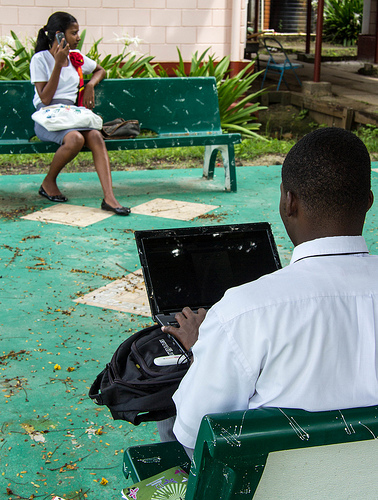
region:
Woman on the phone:
[22, 7, 136, 214]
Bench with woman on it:
[3, 76, 248, 147]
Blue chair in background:
[249, 30, 305, 84]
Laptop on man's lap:
[125, 222, 293, 330]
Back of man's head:
[262, 126, 373, 298]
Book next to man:
[118, 467, 187, 494]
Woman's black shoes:
[33, 180, 122, 212]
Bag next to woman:
[99, 108, 144, 138]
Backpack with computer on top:
[99, 317, 167, 414]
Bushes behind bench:
[111, 32, 261, 135]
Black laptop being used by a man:
[119, 200, 304, 325]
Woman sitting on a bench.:
[23, 20, 139, 233]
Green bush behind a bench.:
[155, 46, 270, 140]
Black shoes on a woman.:
[25, 177, 179, 227]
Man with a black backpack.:
[93, 321, 206, 416]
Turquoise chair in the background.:
[256, 35, 315, 96]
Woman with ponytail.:
[26, 11, 76, 54]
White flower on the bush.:
[107, 28, 149, 56]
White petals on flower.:
[101, 26, 182, 71]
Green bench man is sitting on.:
[199, 415, 368, 481]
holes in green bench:
[160, 86, 226, 129]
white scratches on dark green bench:
[282, 413, 319, 453]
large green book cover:
[103, 462, 219, 498]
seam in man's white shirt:
[192, 303, 301, 396]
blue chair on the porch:
[260, 24, 313, 89]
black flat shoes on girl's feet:
[91, 188, 158, 221]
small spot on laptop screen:
[163, 241, 202, 255]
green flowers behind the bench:
[187, 43, 302, 150]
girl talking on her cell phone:
[42, 22, 79, 57]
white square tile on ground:
[13, 184, 165, 244]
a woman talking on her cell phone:
[18, 8, 142, 218]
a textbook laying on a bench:
[105, 468, 203, 498]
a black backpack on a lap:
[87, 325, 193, 427]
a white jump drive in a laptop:
[154, 344, 194, 374]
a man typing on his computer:
[127, 127, 374, 416]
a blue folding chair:
[261, 25, 308, 90]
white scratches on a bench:
[273, 411, 342, 449]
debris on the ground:
[38, 431, 88, 485]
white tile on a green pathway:
[24, 200, 110, 236]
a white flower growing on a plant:
[113, 23, 141, 67]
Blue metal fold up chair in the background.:
[262, 33, 305, 88]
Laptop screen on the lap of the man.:
[136, 229, 274, 306]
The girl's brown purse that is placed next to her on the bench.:
[102, 114, 140, 141]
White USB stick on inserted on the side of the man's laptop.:
[156, 351, 186, 365]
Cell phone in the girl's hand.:
[55, 32, 68, 48]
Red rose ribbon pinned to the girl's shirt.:
[67, 50, 88, 104]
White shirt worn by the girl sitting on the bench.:
[34, 54, 85, 108]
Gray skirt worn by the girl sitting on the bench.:
[36, 98, 105, 142]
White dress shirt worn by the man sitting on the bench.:
[202, 269, 377, 408]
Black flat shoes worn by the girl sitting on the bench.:
[37, 181, 132, 216]